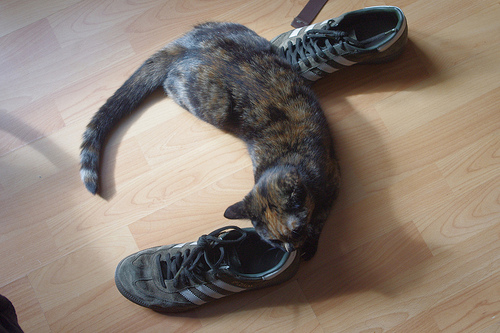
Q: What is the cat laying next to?
A: Sneakers.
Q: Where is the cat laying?
A: On the floor.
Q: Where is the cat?
A: On the floor.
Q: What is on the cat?
A: A tail.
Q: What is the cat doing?
A: Playing on the floor.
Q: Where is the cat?
A: On the floor.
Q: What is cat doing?
A: Playing with sneakers.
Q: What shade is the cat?
A: Brown and black.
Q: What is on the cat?
A: A tail.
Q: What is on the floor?
A: Shadows.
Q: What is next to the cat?
A: A sneaker.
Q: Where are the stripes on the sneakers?
A: On the side.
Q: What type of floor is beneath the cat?
A: Wood.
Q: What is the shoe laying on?
A: Wood floor.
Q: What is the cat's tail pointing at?
A: A shoe.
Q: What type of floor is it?
A: Wooden floor.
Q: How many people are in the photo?
A: 0.